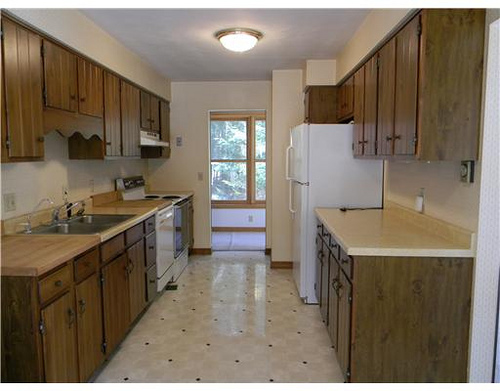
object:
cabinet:
[2, 18, 48, 160]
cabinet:
[40, 34, 80, 117]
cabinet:
[101, 68, 125, 159]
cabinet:
[74, 55, 108, 124]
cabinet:
[118, 77, 144, 159]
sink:
[19, 211, 121, 234]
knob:
[71, 94, 77, 104]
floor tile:
[90, 249, 341, 380]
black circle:
[169, 358, 174, 362]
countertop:
[315, 196, 475, 257]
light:
[214, 29, 264, 54]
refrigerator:
[285, 122, 384, 302]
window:
[211, 120, 249, 203]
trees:
[211, 118, 246, 198]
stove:
[115, 174, 188, 282]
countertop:
[88, 187, 174, 215]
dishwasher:
[155, 200, 175, 293]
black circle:
[234, 359, 240, 364]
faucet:
[49, 199, 80, 224]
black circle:
[144, 341, 150, 347]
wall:
[382, 157, 481, 234]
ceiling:
[82, 9, 375, 83]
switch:
[458, 160, 475, 185]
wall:
[2, 126, 146, 219]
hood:
[142, 126, 172, 145]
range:
[116, 171, 191, 284]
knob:
[75, 92, 86, 104]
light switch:
[3, 190, 16, 214]